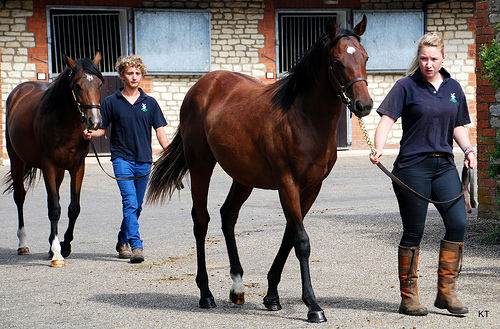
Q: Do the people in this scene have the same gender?
A: No, they are both male and female.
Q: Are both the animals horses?
A: Yes, all the animals are horses.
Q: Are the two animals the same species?
A: Yes, all the animals are horses.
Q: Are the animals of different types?
A: No, all the animals are horses.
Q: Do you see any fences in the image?
A: No, there are no fences.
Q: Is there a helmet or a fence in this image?
A: No, there are no fences or helmets.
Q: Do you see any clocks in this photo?
A: No, there are no clocks.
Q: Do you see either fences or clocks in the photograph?
A: No, there are no clocks or fences.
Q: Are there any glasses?
A: No, there are no glasses.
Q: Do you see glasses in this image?
A: No, there are no glasses.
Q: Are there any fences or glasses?
A: No, there are no glasses or fences.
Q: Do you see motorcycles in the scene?
A: No, there are no motorcycles.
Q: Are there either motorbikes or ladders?
A: No, there are no motorbikes or ladders.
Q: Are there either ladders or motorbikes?
A: No, there are no motorbikes or ladders.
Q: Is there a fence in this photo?
A: No, there are no fences.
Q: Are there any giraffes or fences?
A: No, there are no fences or giraffes.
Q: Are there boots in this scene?
A: Yes, there are boots.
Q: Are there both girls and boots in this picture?
A: Yes, there are both boots and a girl.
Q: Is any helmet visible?
A: No, there are no helmets.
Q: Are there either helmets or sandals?
A: No, there are no helmets or sandals.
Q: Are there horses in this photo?
A: Yes, there is a horse.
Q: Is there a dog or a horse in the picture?
A: Yes, there is a horse.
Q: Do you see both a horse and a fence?
A: No, there is a horse but no fences.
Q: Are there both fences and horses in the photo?
A: No, there is a horse but no fences.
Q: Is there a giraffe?
A: No, there are no giraffes.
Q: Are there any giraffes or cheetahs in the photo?
A: No, there are no giraffes or cheetahs.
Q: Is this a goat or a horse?
A: This is a horse.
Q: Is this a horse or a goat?
A: This is a horse.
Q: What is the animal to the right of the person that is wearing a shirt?
A: The animal is a horse.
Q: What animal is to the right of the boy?
A: The animal is a horse.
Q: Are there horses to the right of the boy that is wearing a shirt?
A: Yes, there is a horse to the right of the boy.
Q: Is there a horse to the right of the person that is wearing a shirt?
A: Yes, there is a horse to the right of the boy.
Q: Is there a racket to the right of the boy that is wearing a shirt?
A: No, there is a horse to the right of the boy.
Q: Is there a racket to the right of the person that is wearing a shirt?
A: No, there is a horse to the right of the boy.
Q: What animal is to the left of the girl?
A: The animal is a horse.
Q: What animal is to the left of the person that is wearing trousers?
A: The animal is a horse.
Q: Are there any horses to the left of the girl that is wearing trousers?
A: Yes, there is a horse to the left of the girl.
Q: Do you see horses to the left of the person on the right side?
A: Yes, there is a horse to the left of the girl.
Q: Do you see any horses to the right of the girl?
A: No, the horse is to the left of the girl.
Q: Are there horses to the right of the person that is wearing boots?
A: No, the horse is to the left of the girl.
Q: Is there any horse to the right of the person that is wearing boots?
A: No, the horse is to the left of the girl.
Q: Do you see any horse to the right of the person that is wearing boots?
A: No, the horse is to the left of the girl.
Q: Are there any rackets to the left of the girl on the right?
A: No, there is a horse to the left of the girl.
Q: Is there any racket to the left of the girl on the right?
A: No, there is a horse to the left of the girl.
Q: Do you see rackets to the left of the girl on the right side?
A: No, there is a horse to the left of the girl.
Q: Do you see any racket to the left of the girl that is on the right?
A: No, there is a horse to the left of the girl.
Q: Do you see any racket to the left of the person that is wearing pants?
A: No, there is a horse to the left of the girl.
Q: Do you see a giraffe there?
A: No, there are no giraffes.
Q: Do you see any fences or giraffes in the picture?
A: No, there are no giraffes or fences.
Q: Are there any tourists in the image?
A: No, there are no tourists.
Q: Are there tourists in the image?
A: No, there are no tourists.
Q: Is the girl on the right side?
A: Yes, the girl is on the right of the image.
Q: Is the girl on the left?
A: No, the girl is on the right of the image.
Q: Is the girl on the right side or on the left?
A: The girl is on the right of the image.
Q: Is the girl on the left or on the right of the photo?
A: The girl is on the right of the image.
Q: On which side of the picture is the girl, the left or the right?
A: The girl is on the right of the image.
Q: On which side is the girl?
A: The girl is on the right of the image.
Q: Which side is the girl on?
A: The girl is on the right of the image.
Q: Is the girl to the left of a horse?
A: No, the girl is to the right of a horse.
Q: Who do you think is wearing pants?
A: The girl is wearing pants.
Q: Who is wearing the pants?
A: The girl is wearing pants.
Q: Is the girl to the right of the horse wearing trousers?
A: Yes, the girl is wearing trousers.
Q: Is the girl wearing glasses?
A: No, the girl is wearing trousers.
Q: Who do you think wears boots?
A: The girl wears boots.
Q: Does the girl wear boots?
A: Yes, the girl wears boots.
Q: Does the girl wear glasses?
A: No, the girl wears boots.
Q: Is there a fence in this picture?
A: No, there are no fences.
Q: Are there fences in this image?
A: No, there are no fences.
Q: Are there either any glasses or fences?
A: No, there are no fences or glasses.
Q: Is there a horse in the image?
A: Yes, there is a horse.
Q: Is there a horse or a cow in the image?
A: Yes, there is a horse.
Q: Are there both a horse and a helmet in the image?
A: No, there is a horse but no helmets.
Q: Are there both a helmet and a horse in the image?
A: No, there is a horse but no helmets.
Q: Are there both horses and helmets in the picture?
A: No, there is a horse but no helmets.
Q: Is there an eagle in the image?
A: No, there are no eagles.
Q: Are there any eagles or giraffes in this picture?
A: No, there are no eagles or giraffes.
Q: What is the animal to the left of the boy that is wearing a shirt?
A: The animal is a horse.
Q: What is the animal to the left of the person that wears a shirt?
A: The animal is a horse.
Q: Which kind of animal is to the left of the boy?
A: The animal is a horse.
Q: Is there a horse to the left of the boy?
A: Yes, there is a horse to the left of the boy.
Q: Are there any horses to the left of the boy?
A: Yes, there is a horse to the left of the boy.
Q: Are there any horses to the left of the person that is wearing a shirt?
A: Yes, there is a horse to the left of the boy.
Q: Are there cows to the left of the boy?
A: No, there is a horse to the left of the boy.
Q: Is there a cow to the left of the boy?
A: No, there is a horse to the left of the boy.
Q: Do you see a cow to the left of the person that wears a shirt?
A: No, there is a horse to the left of the boy.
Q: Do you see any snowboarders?
A: No, there are no snowboarders.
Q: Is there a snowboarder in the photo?
A: No, there are no snowboarders.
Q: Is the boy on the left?
A: Yes, the boy is on the left of the image.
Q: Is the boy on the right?
A: No, the boy is on the left of the image.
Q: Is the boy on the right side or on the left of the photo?
A: The boy is on the left of the image.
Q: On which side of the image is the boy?
A: The boy is on the left of the image.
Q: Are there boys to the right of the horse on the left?
A: Yes, there is a boy to the right of the horse.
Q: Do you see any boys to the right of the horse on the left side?
A: Yes, there is a boy to the right of the horse.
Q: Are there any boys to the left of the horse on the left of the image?
A: No, the boy is to the right of the horse.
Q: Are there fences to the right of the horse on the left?
A: No, there is a boy to the right of the horse.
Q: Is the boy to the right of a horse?
A: Yes, the boy is to the right of a horse.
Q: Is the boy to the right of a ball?
A: No, the boy is to the right of a horse.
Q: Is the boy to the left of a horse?
A: No, the boy is to the right of a horse.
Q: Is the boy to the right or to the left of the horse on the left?
A: The boy is to the right of the horse.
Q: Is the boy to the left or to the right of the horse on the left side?
A: The boy is to the right of the horse.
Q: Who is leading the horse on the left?
A: The boy is leading the horse.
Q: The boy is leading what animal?
A: The boy is leading the horse.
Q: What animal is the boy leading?
A: The boy is leading the horse.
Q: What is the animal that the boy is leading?
A: The animal is a horse.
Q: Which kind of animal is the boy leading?
A: The boy is leading the horse.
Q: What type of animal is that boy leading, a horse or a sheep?
A: The boy is leading a horse.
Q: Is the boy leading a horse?
A: Yes, the boy is leading a horse.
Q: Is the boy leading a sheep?
A: No, the boy is leading a horse.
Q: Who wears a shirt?
A: The boy wears a shirt.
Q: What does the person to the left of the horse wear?
A: The boy wears a shirt.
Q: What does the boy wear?
A: The boy wears a shirt.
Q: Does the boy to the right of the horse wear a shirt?
A: Yes, the boy wears a shirt.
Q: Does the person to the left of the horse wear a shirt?
A: Yes, the boy wears a shirt.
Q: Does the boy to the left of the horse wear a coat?
A: No, the boy wears a shirt.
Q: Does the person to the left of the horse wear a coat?
A: No, the boy wears a shirt.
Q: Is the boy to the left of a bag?
A: No, the boy is to the left of a horse.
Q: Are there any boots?
A: Yes, there are boots.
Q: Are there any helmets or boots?
A: Yes, there are boots.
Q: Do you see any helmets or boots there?
A: Yes, there are boots.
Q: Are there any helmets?
A: No, there are no helmets.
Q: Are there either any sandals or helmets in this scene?
A: No, there are no helmets or sandals.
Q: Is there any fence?
A: No, there are no fences.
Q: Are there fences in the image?
A: No, there are no fences.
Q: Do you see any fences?
A: No, there are no fences.